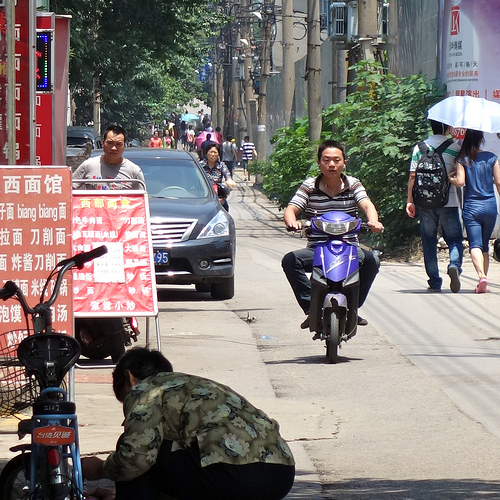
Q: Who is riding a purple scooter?
A: A man.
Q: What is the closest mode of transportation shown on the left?
A: Bicycle.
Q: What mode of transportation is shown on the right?
A: Motorcycyle.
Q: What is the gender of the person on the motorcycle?
A: Male.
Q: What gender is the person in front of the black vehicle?
A: Male.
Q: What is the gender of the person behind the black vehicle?
A: Female.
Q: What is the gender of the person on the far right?
A: Female.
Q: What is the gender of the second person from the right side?
A: Male.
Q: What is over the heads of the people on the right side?
A: Umbrella.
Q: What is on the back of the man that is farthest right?
A: Backpack.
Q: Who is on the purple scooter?
A: A man.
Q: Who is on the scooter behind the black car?
A: A woman.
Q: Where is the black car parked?
A: On the sidewalk.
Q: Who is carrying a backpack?
A: A man.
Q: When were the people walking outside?
A: During daylight hours.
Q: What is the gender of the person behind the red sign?
A: Male.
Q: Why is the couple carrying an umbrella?
A: To shade the sun.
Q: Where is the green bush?
A: Beside the building.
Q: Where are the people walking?
A: In a downtown area.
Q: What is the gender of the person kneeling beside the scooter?
A: Male.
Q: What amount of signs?
A: Two.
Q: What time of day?
A: Daylight.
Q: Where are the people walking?
A: Street.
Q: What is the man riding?
A: Moped.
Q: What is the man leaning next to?
A: Bike.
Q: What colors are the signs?
A: Red.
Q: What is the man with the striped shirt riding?
A: A moped.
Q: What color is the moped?
A: Blue.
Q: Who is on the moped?
A: A man.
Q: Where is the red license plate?
A: On the moped.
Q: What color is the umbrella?
A: White.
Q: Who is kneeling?
A: A woman.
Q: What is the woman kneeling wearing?
A: A flowered shirt.